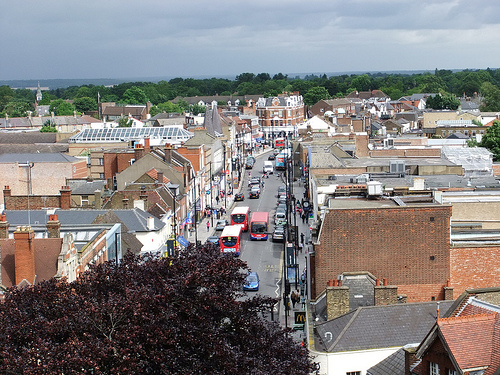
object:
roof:
[71, 127, 189, 140]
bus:
[250, 212, 268, 240]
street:
[178, 134, 302, 332]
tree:
[68, 287, 219, 363]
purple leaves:
[25, 290, 93, 371]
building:
[315, 200, 463, 338]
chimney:
[160, 144, 172, 164]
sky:
[0, 1, 499, 81]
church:
[32, 81, 63, 123]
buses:
[218, 224, 243, 254]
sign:
[294, 308, 310, 328]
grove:
[278, 80, 468, 91]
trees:
[134, 79, 272, 95]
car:
[241, 270, 260, 290]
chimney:
[13, 227, 38, 287]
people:
[300, 231, 305, 245]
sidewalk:
[293, 182, 309, 269]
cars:
[273, 230, 285, 240]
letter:
[163, 236, 195, 265]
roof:
[439, 316, 498, 371]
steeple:
[35, 80, 50, 119]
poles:
[283, 173, 308, 330]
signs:
[206, 189, 210, 194]